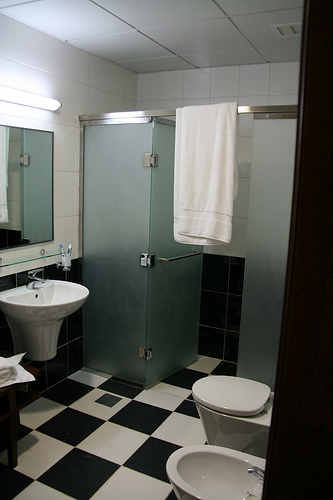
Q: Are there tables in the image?
A: Yes, there is a table.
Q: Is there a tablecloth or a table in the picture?
A: Yes, there is a table.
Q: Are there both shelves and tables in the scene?
A: Yes, there are both a table and a shelf.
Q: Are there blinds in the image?
A: No, there are no blinds.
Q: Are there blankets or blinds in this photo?
A: No, there are no blinds or blankets.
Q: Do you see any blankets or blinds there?
A: No, there are no blinds or blankets.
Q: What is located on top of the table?
A: The towels are on top of the table.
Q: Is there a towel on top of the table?
A: Yes, there are towels on top of the table.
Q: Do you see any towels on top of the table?
A: Yes, there are towels on top of the table.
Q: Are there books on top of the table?
A: No, there are towels on top of the table.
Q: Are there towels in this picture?
A: Yes, there is a towel.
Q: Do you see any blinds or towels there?
A: Yes, there is a towel.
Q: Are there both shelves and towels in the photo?
A: Yes, there are both a towel and a shelf.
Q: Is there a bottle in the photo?
A: No, there are no bottles.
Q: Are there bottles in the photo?
A: No, there are no bottles.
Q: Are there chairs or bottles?
A: No, there are no bottles or chairs.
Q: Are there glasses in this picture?
A: No, there are no glasses.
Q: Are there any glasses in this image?
A: No, there are no glasses.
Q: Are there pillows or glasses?
A: No, there are no glasses or pillows.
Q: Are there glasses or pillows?
A: No, there are no glasses or pillows.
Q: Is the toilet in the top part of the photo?
A: No, the toilet is in the bottom of the image.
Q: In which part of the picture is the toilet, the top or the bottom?
A: The toilet is in the bottom of the image.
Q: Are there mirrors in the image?
A: Yes, there is a mirror.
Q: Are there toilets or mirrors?
A: Yes, there is a mirror.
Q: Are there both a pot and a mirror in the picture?
A: No, there is a mirror but no pots.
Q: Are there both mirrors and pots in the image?
A: No, there is a mirror but no pots.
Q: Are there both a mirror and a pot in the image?
A: No, there is a mirror but no pots.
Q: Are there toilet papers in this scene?
A: No, there are no toilet papers.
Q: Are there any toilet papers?
A: No, there are no toilet papers.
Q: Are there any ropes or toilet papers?
A: No, there are no toilet papers or ropes.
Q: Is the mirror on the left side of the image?
A: Yes, the mirror is on the left of the image.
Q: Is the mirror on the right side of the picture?
A: No, the mirror is on the left of the image.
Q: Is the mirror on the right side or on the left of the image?
A: The mirror is on the left of the image.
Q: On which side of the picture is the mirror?
A: The mirror is on the left of the image.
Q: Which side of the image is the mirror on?
A: The mirror is on the left of the image.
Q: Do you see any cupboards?
A: No, there are no cupboards.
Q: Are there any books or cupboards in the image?
A: No, there are no cupboards or books.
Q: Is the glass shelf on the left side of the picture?
A: Yes, the shelf is on the left of the image.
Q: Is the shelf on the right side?
A: No, the shelf is on the left of the image.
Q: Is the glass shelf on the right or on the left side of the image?
A: The shelf is on the left of the image.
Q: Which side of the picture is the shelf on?
A: The shelf is on the left of the image.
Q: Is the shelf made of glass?
A: Yes, the shelf is made of glass.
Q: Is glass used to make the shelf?
A: Yes, the shelf is made of glass.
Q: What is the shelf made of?
A: The shelf is made of glass.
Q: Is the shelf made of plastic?
A: No, the shelf is made of glass.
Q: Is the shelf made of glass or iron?
A: The shelf is made of glass.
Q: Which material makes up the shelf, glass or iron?
A: The shelf is made of glass.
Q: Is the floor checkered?
A: Yes, the floor is checkered.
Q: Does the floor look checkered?
A: Yes, the floor is checkered.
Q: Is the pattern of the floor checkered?
A: Yes, the floor is checkered.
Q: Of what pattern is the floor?
A: The floor is checkered.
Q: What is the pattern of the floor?
A: The floor is checkered.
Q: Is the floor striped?
A: No, the floor is checkered.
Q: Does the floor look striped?
A: No, the floor is checkered.